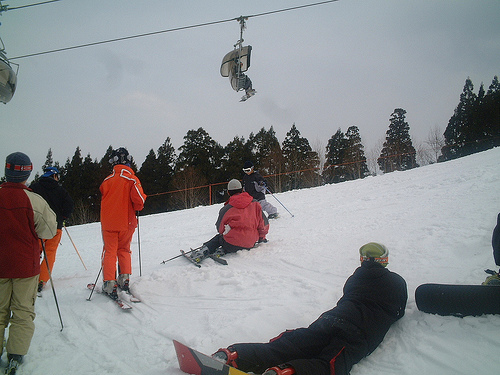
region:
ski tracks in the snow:
[49, 334, 133, 354]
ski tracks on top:
[168, 285, 283, 324]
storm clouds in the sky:
[57, 83, 174, 106]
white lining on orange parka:
[112, 165, 152, 195]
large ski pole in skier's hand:
[80, 269, 110, 294]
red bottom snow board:
[168, 339, 194, 371]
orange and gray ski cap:
[5, 151, 44, 192]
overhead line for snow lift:
[67, 14, 222, 59]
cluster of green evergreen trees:
[191, 130, 488, 207]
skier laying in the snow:
[167, 156, 309, 276]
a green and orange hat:
[350, 230, 394, 280]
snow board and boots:
[133, 340, 303, 373]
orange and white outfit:
[92, 184, 147, 318]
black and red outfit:
[257, 271, 398, 363]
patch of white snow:
[315, 200, 353, 251]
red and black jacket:
[185, 191, 269, 273]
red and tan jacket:
[0, 186, 60, 271]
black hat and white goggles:
[235, 145, 267, 175]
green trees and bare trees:
[152, 123, 224, 215]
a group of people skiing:
[20, 155, 293, 373]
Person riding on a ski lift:
[213, 9, 273, 108]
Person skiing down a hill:
[240, 166, 298, 221]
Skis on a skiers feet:
[81, 272, 173, 313]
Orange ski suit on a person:
[97, 156, 152, 280]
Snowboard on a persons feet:
[161, 330, 293, 373]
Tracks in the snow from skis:
[147, 286, 255, 318]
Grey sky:
[12, 109, 118, 144]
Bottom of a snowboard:
[413, 281, 498, 317]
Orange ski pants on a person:
[38, 227, 69, 294]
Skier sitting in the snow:
[156, 176, 269, 268]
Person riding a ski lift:
[204, 18, 294, 103]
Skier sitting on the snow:
[156, 175, 273, 284]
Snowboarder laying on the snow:
[156, 236, 427, 373]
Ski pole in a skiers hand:
[36, 235, 79, 337]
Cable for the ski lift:
[16, 48, 93, 66]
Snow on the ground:
[382, 178, 458, 240]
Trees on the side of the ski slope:
[436, 70, 498, 167]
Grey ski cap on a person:
[224, 177, 248, 195]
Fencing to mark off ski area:
[162, 182, 221, 206]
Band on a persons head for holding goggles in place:
[356, 255, 401, 265]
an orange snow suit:
[81, 154, 156, 298]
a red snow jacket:
[208, 197, 280, 255]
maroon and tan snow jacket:
[1, 183, 61, 285]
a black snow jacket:
[203, 247, 415, 372]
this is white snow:
[352, 177, 402, 224]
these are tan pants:
[0, 264, 49, 356]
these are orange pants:
[91, 221, 146, 289]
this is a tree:
[370, 105, 427, 185]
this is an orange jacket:
[94, 167, 151, 237]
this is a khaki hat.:
[348, 238, 402, 279]